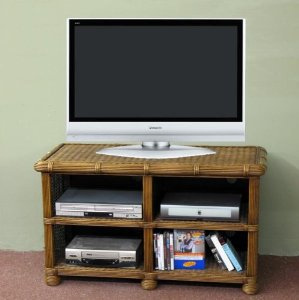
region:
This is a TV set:
[53, 10, 249, 144]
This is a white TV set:
[55, 14, 257, 154]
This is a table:
[37, 137, 265, 298]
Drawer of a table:
[47, 169, 144, 224]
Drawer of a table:
[149, 173, 254, 226]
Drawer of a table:
[51, 220, 149, 276]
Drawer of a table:
[152, 221, 247, 274]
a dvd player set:
[53, 184, 146, 219]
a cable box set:
[157, 191, 244, 225]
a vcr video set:
[62, 234, 145, 267]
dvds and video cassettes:
[155, 226, 247, 273]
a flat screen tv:
[58, 15, 254, 146]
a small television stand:
[30, 141, 272, 299]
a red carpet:
[3, 243, 293, 298]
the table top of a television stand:
[40, 132, 270, 176]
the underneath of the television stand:
[43, 269, 260, 295]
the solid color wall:
[4, 128, 33, 240]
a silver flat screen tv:
[59, 11, 259, 163]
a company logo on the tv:
[145, 119, 168, 135]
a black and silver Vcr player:
[58, 235, 138, 266]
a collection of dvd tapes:
[150, 232, 174, 269]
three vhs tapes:
[204, 234, 242, 273]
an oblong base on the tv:
[99, 143, 218, 160]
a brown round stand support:
[40, 272, 68, 287]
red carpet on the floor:
[6, 254, 33, 286]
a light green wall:
[1, 9, 59, 142]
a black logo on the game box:
[193, 207, 204, 219]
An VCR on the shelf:
[63, 230, 142, 270]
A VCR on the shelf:
[53, 186, 144, 224]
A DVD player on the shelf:
[157, 188, 242, 221]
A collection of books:
[205, 233, 246, 270]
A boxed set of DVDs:
[170, 227, 206, 269]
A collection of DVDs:
[153, 230, 174, 271]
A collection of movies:
[150, 229, 204, 270]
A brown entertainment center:
[27, 144, 269, 293]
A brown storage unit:
[19, 142, 272, 295]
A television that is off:
[50, 7, 256, 160]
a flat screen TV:
[64, 18, 245, 141]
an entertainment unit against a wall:
[36, 142, 268, 291]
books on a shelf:
[206, 232, 242, 271]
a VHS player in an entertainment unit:
[64, 233, 138, 264]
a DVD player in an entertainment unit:
[54, 188, 140, 215]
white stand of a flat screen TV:
[94, 143, 217, 157]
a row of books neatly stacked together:
[151, 231, 171, 269]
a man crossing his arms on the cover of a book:
[179, 231, 194, 252]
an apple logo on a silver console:
[197, 209, 202, 216]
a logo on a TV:
[148, 125, 162, 130]